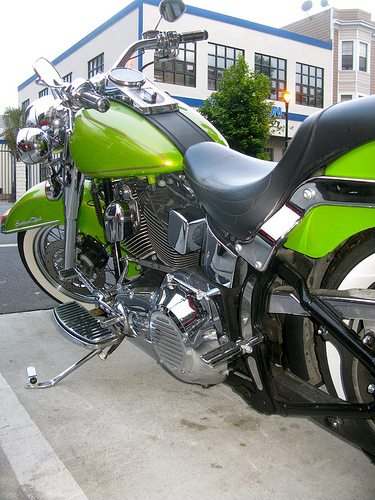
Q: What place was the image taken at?
A: It was taken at the parking lot.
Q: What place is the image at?
A: It is at the parking lot.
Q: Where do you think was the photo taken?
A: It was taken at the parking lot.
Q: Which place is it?
A: It is a parking lot.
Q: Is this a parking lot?
A: Yes, it is a parking lot.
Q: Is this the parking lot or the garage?
A: It is the parking lot.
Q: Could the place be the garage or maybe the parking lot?
A: It is the parking lot.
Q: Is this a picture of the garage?
A: No, the picture is showing the parking lot.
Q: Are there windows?
A: Yes, there are windows.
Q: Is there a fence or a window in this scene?
A: Yes, there are windows.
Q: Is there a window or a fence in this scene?
A: Yes, there are windows.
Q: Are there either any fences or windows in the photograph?
A: Yes, there are windows.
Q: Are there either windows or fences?
A: Yes, there are windows.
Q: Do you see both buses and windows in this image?
A: No, there are windows but no buses.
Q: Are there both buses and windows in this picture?
A: No, there are windows but no buses.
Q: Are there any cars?
A: No, there are no cars.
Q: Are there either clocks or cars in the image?
A: No, there are no cars or clocks.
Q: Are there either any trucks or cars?
A: No, there are no cars or trucks.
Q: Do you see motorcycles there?
A: Yes, there is a motorcycle.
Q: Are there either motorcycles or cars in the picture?
A: Yes, there is a motorcycle.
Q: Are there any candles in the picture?
A: No, there are no candles.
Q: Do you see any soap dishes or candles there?
A: No, there are no candles or soap dishes.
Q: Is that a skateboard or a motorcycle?
A: That is a motorcycle.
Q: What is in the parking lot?
A: The motorbike is in the parking lot.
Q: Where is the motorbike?
A: The motorbike is in the parking lot.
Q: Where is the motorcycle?
A: The motorbike is in the parking lot.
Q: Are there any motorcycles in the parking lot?
A: Yes, there is a motorcycle in the parking lot.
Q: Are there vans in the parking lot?
A: No, there is a motorcycle in the parking lot.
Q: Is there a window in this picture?
A: Yes, there are windows.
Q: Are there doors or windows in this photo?
A: Yes, there are windows.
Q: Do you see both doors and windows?
A: No, there are windows but no doors.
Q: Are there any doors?
A: No, there are no doors.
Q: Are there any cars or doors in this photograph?
A: No, there are no doors or cars.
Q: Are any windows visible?
A: Yes, there are windows.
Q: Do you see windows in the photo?
A: Yes, there are windows.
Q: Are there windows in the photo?
A: Yes, there are windows.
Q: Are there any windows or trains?
A: Yes, there are windows.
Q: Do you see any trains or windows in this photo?
A: Yes, there are windows.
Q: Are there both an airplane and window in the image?
A: No, there are windows but no airplanes.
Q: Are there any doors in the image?
A: No, there are no doors.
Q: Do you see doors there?
A: No, there are no doors.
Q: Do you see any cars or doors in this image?
A: No, there are no doors or cars.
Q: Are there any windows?
A: Yes, there are windows.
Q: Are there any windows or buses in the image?
A: Yes, there are windows.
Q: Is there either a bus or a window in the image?
A: Yes, there are windows.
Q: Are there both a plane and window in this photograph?
A: No, there are windows but no airplanes.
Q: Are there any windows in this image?
A: Yes, there are windows.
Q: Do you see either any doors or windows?
A: Yes, there are windows.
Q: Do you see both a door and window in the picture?
A: No, there are windows but no doors.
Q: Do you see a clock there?
A: No, there are no clocks.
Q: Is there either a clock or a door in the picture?
A: No, there are no clocks or doors.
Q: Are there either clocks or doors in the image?
A: No, there are no clocks or doors.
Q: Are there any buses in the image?
A: No, there are no buses.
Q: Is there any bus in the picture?
A: No, there are no buses.